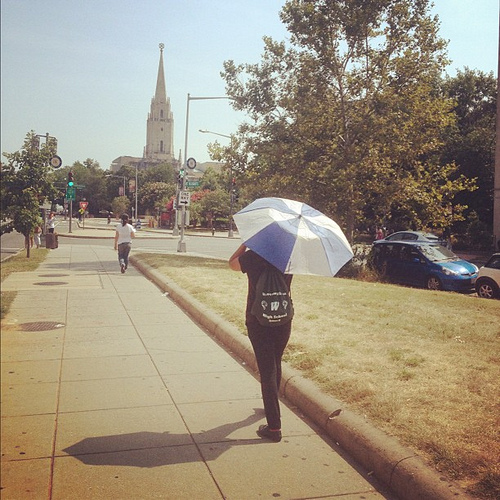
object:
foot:
[255, 420, 282, 440]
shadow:
[62, 401, 280, 470]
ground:
[1, 215, 500, 498]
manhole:
[11, 316, 68, 335]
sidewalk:
[0, 239, 405, 499]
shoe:
[257, 421, 285, 444]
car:
[367, 228, 484, 293]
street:
[0, 220, 500, 499]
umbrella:
[230, 196, 358, 279]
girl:
[226, 223, 304, 447]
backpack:
[249, 265, 298, 329]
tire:
[423, 275, 441, 295]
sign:
[175, 188, 197, 210]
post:
[176, 207, 194, 250]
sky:
[0, 0, 500, 172]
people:
[110, 211, 139, 273]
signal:
[67, 178, 74, 196]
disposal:
[41, 225, 59, 250]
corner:
[14, 240, 133, 258]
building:
[108, 41, 183, 232]